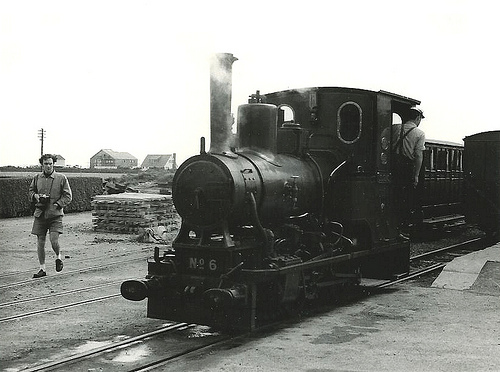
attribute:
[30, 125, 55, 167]
pole — electric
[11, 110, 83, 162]
pole — electric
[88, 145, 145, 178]
building — white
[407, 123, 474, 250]
passenger car — black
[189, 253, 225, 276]
number — 6